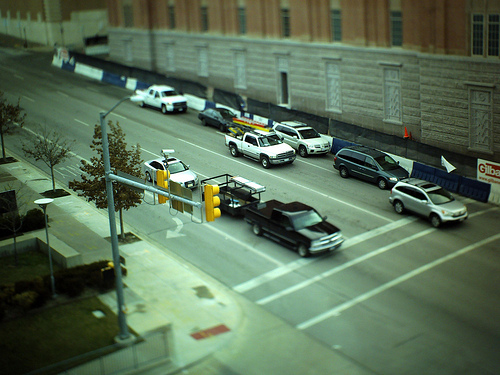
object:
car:
[224, 129, 298, 170]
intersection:
[199, 277, 252, 356]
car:
[143, 155, 200, 191]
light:
[200, 182, 222, 224]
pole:
[107, 173, 202, 208]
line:
[296, 230, 497, 329]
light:
[126, 92, 147, 103]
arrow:
[166, 217, 187, 239]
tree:
[64, 113, 151, 242]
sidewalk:
[0, 143, 256, 375]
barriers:
[425, 162, 499, 208]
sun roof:
[417, 181, 442, 192]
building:
[0, 0, 500, 168]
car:
[241, 197, 348, 258]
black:
[288, 204, 301, 211]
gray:
[409, 203, 426, 210]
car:
[128, 83, 189, 115]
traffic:
[157, 168, 172, 205]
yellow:
[158, 170, 163, 187]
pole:
[97, 113, 128, 341]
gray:
[110, 200, 114, 229]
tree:
[17, 119, 78, 194]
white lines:
[358, 263, 430, 300]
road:
[0, 37, 500, 375]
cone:
[402, 125, 411, 141]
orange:
[405, 130, 407, 137]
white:
[168, 232, 177, 236]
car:
[198, 107, 239, 133]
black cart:
[201, 171, 267, 218]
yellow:
[206, 186, 213, 210]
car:
[333, 143, 411, 192]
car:
[271, 119, 334, 158]